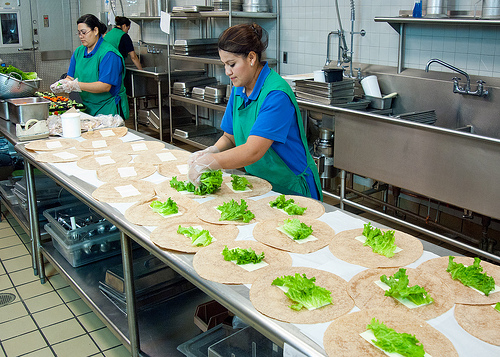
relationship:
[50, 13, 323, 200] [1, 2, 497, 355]
three women inside a kitchen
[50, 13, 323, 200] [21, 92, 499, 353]
women assembling food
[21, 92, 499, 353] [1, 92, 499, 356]
tortillas on top of tables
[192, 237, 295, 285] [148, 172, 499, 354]
tortilla have lettuce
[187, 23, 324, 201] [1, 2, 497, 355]
worker in kitchen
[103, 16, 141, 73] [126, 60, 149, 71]
woman washing plates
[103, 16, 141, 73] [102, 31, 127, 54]
woman wearing green apron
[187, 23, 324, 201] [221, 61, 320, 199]
woman wearing blue shirt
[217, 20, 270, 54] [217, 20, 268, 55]
hairnet covering hair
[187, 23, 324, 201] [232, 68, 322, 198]
woman has apron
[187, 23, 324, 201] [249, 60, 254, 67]
woman has earrings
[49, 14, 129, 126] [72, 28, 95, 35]
woman has eyeglasses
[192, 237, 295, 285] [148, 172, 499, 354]
tortilla has lettuce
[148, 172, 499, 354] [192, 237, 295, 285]
green lettuce on top of tortilla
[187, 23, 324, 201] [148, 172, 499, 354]
woman cutting lettuce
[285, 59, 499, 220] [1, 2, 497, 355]
silver sink inside kitchen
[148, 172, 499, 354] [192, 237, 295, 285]
lettuce on top of tortilla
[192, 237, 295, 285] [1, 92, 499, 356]
tortilla on top of counter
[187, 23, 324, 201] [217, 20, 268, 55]
woman has brown hair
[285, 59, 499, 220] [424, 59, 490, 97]
sink has faucet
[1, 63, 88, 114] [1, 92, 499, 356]
vegetables on top of counter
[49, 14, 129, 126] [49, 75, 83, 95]
woman wearing gloves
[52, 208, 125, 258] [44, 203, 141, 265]
utensils inside of bin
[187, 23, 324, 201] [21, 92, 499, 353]
woman preparing food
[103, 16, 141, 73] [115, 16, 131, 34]
woman has head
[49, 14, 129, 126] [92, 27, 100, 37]
woman has ear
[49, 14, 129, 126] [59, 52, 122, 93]
woman has arm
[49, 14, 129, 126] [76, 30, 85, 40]
woman has nose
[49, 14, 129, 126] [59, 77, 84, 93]
woman has hand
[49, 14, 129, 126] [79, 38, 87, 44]
woman has mouth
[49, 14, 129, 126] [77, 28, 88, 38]
woman has eye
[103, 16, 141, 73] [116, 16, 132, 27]
woman has black hair